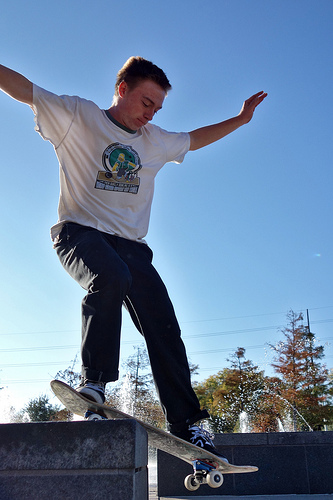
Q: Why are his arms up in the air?
A: Balance.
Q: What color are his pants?
A: Black.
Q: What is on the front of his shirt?
A: Logo.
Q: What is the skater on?
A: Skateboard.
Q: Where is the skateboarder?
A: Skate park.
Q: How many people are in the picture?
A: One.